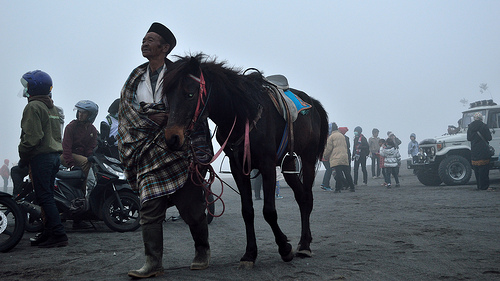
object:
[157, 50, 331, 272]
horse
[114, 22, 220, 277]
man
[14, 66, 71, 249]
man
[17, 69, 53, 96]
helmet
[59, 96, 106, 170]
man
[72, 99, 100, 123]
helmet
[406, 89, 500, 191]
truck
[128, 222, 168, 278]
boot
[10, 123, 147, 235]
motorcycle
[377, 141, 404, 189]
person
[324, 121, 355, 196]
person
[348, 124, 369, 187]
person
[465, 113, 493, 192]
person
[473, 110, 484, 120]
hat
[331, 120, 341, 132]
hat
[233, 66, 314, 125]
saddle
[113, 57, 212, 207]
blanket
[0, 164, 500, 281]
beach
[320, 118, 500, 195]
group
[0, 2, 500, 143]
sky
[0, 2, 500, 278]
day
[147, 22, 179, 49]
hat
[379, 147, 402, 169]
coat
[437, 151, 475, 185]
tire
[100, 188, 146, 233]
wheel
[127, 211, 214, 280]
pair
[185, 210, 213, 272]
boot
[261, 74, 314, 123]
back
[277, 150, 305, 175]
stirrup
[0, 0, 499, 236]
background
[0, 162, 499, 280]
sand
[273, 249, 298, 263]
hoof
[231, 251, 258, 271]
hoof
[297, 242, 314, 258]
hoof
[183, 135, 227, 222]
rope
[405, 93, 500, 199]
jeep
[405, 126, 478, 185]
end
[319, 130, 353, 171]
jacket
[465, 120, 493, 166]
jacket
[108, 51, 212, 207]
warm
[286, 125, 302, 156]
strap